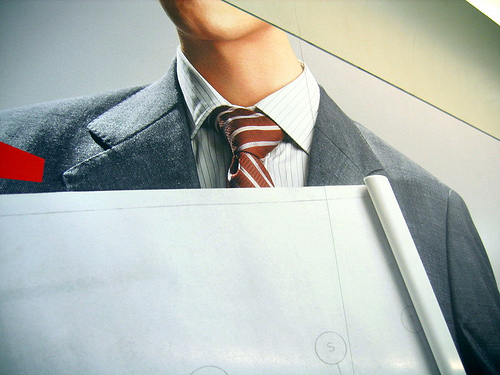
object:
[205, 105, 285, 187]
tie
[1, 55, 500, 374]
suit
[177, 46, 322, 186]
shirt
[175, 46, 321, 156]
collar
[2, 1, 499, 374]
ad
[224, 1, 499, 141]
wall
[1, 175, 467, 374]
paper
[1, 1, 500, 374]
man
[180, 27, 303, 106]
neck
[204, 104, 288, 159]
knot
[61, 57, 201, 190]
lapel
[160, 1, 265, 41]
chin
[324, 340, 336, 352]
letter s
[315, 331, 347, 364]
circle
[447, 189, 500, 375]
sleeve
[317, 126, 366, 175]
stiching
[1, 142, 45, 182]
object